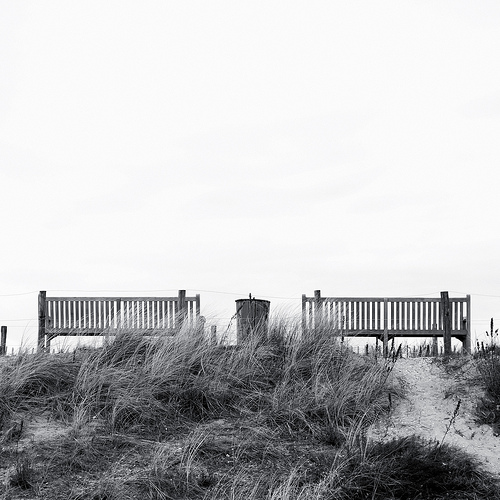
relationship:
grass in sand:
[1, 307, 498, 498] [379, 354, 499, 473]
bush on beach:
[474, 337, 495, 410] [40, 349, 496, 455]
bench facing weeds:
[30, 281, 212, 358] [19, 331, 310, 450]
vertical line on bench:
[84, 301, 94, 328] [35, 290, 202, 347]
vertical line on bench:
[163, 301, 169, 324] [35, 290, 202, 347]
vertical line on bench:
[59, 300, 64, 327] [35, 290, 202, 347]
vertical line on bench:
[110, 302, 115, 324] [35, 290, 202, 347]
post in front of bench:
[442, 291, 452, 356] [301, 294, 471, 351]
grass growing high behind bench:
[1, 307, 498, 498] [38, 290, 470, 354]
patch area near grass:
[396, 353, 463, 438] [46, 343, 399, 478]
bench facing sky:
[298, 287, 484, 349] [16, 148, 478, 285]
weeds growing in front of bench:
[1, 301, 498, 498] [34, 287, 200, 354]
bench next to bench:
[35, 290, 202, 353] [293, 278, 478, 368]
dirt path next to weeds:
[356, 338, 498, 484] [16, 324, 404, 482]